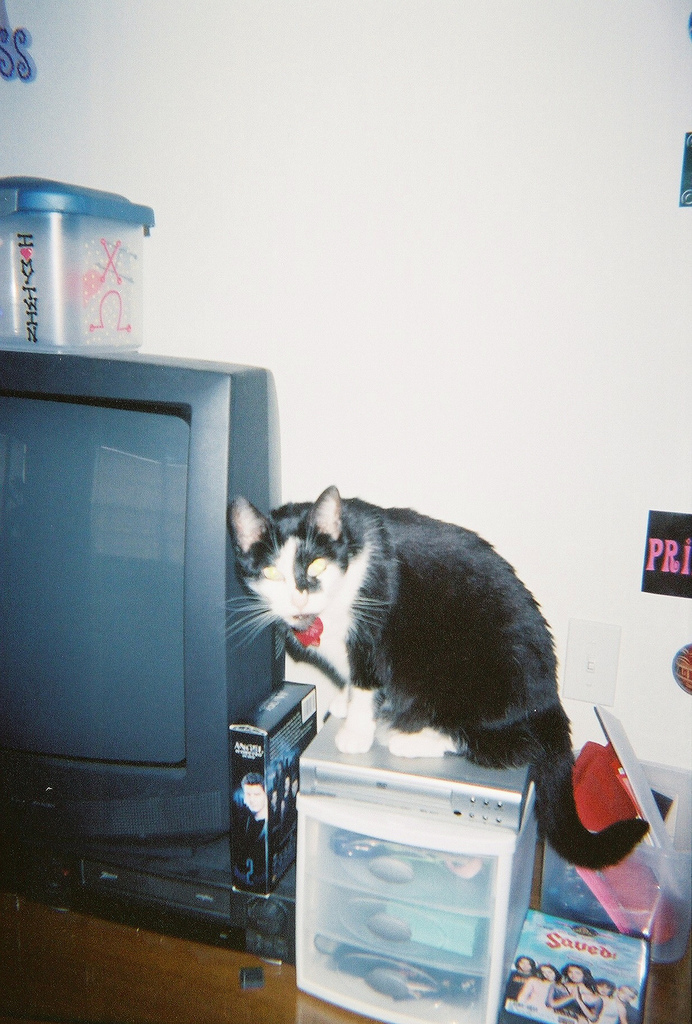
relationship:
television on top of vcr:
[0, 350, 299, 846] [10, 847, 304, 965]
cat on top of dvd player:
[226, 475, 657, 875] [283, 700, 545, 839]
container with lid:
[2, 202, 149, 355] [3, 168, 160, 235]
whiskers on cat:
[211, 584, 392, 638] [226, 475, 657, 875]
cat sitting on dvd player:
[226, 475, 657, 875] [283, 678, 550, 828]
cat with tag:
[226, 475, 657, 875] [286, 604, 325, 651]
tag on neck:
[286, 604, 325, 651] [271, 487, 398, 645]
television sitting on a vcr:
[6, 325, 290, 860] [10, 857, 327, 968]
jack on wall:
[551, 609, 626, 718] [6, 2, 671, 761]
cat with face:
[226, 475, 657, 875] [228, 491, 355, 631]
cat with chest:
[226, 475, 657, 875] [278, 577, 383, 690]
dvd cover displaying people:
[500, 896, 667, 1018] [500, 941, 635, 1020]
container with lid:
[527, 726, 671, 958] [583, 691, 668, 860]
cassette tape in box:
[239, 684, 311, 885] [225, 681, 323, 907]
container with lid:
[0, 176, 155, 351] [3, 168, 160, 235]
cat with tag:
[226, 475, 657, 875] [293, 616, 324, 648]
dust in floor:
[226, 958, 263, 988] [7, 721, 671, 1010]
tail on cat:
[538, 745, 647, 868] [228, 491, 570, 774]